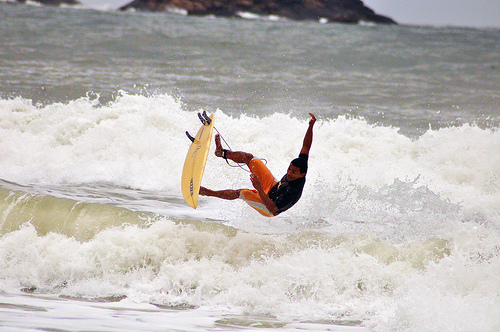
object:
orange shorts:
[239, 156, 279, 217]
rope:
[213, 125, 267, 172]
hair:
[291, 158, 308, 177]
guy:
[198, 113, 317, 218]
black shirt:
[268, 153, 309, 216]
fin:
[198, 111, 212, 126]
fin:
[185, 131, 195, 143]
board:
[181, 112, 215, 208]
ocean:
[0, 8, 498, 332]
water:
[0, 7, 500, 332]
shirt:
[269, 153, 309, 216]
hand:
[309, 112, 317, 126]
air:
[0, 1, 498, 225]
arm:
[298, 127, 313, 160]